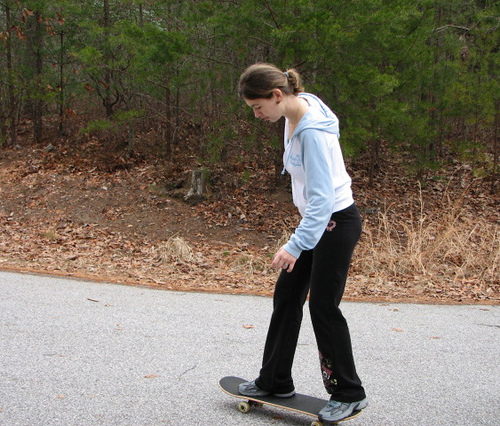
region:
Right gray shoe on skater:
[234, 364, 302, 411]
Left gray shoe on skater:
[309, 391, 373, 423]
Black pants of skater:
[250, 201, 375, 402]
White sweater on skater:
[267, 88, 371, 265]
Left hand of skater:
[254, 244, 305, 276]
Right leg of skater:
[251, 255, 311, 401]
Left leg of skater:
[303, 248, 373, 409]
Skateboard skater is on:
[211, 371, 365, 420]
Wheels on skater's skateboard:
[232, 400, 325, 424]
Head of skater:
[227, 56, 307, 130]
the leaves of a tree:
[371, 45, 416, 106]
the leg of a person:
[307, 265, 362, 397]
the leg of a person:
[255, 271, 302, 386]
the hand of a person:
[268, 247, 298, 272]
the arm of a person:
[295, 137, 332, 248]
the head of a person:
[235, 60, 300, 120]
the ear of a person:
[270, 85, 280, 100]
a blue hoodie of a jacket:
[303, 90, 341, 133]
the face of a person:
[246, 96, 276, 126]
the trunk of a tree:
[101, 71, 113, 117]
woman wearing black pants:
[299, 212, 366, 399]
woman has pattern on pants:
[323, 348, 337, 403]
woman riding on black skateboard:
[224, 375, 301, 421]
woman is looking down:
[245, 109, 322, 164]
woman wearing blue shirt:
[286, 133, 347, 245]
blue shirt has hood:
[318, 103, 347, 155]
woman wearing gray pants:
[236, 377, 294, 424]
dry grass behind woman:
[418, 196, 469, 293]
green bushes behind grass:
[373, 113, 428, 164]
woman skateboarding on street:
[128, 321, 178, 375]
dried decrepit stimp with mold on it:
[169, 166, 208, 200]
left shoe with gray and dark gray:
[316, 397, 368, 423]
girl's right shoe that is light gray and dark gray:
[235, 379, 299, 399]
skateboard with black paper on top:
[217, 374, 362, 423]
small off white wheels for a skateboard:
[235, 397, 325, 424]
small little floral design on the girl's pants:
[311, 349, 337, 391]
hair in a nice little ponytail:
[280, 66, 302, 97]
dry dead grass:
[363, 216, 498, 284]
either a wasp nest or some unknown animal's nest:
[450, 31, 470, 58]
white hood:
[299, 88, 341, 131]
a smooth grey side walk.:
[27, 306, 167, 401]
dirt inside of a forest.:
[34, 127, 202, 236]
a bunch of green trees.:
[6, 10, 473, 55]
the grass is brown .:
[401, 215, 493, 292]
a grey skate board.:
[218, 363, 370, 424]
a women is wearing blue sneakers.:
[313, 374, 371, 422]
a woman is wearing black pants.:
[303, 277, 351, 364]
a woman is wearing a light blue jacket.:
[288, 154, 358, 205]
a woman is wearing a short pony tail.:
[236, 62, 313, 96]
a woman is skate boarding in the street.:
[205, 55, 397, 425]